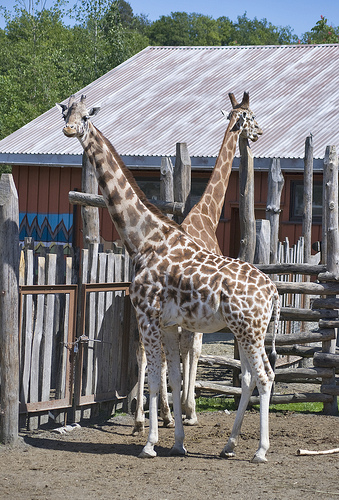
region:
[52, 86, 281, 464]
two giraffes are standing next to each other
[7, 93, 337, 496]
the giraffes are in an enclosure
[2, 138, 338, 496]
the enclosure has a wooden fence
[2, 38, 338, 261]
a building is next to the enclosure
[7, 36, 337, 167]
the building has a metal corrugated roof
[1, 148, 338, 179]
the building's flashing is metal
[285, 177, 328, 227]
a window is in the building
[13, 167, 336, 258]
the wall of the building is red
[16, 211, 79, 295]
a painting is on the side of the building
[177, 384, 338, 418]
green grass is next to the pen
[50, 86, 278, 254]
two giraffes facing opposite directions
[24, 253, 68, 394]
wood boards of fence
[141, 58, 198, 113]
metal roof of building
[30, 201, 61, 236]
blue design on red building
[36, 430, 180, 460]
shadow of giraffe on dirt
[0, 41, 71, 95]
green leaves on trees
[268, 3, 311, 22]
blue of daytime sky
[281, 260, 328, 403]
fence made of logs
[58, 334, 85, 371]
log and chain on fence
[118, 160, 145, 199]
brown mane on giraffe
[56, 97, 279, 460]
giraffe standing by fence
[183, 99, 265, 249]
giraffe looking for food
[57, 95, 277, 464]
brown and white giraffe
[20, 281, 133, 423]
brown metal locked gate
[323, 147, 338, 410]
grey wooden fence post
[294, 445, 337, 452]
grey stick on ground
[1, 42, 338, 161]
grey metal roof panel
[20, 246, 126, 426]
grey wood picket fence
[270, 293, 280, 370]
black and brown tail on giraffe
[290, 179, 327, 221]
glass window in building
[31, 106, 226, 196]
the giraffe has ears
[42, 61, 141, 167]
the giraffe has ears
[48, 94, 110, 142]
the giraffe has ears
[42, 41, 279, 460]
two giraffes looking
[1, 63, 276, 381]
giraffes looking opposite directions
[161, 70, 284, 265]
long neck of giraffe on right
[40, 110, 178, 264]
long neck of giraffe on left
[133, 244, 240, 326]
brown spots on giraffe body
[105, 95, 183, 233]
long brown mane of giraffe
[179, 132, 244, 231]
long brown main of other giraffe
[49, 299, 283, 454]
long white legs of giraffe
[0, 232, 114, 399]
old wooden fence next to animals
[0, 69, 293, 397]
two wild animals standing